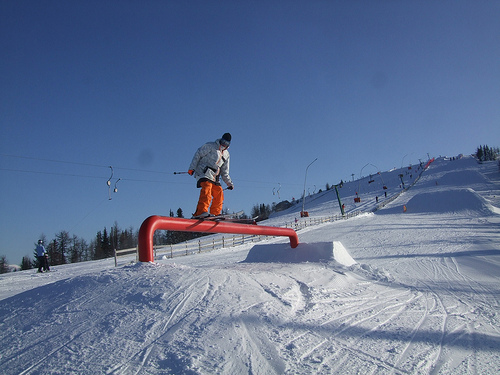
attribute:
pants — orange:
[199, 176, 226, 217]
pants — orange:
[200, 182, 225, 215]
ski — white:
[214, 212, 233, 221]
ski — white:
[189, 212, 218, 220]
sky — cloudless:
[2, 0, 497, 266]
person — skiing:
[130, 88, 252, 252]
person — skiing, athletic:
[187, 131, 234, 220]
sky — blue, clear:
[88, 33, 358, 118]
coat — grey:
[200, 120, 221, 169]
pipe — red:
[138, 217, 298, 263]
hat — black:
[218, 132, 233, 145]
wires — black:
[0, 151, 330, 197]